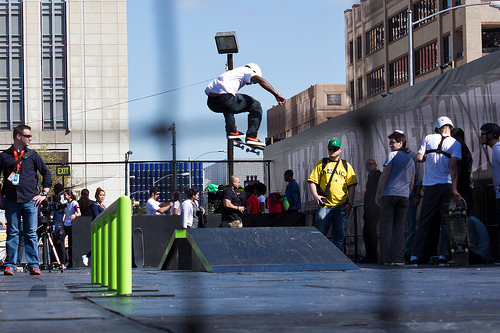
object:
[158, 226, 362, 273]
skateboard ramp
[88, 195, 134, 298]
railing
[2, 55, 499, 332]
skateboard park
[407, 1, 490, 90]
light post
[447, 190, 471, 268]
skateboard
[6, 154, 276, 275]
fence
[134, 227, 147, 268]
skateboard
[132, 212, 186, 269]
wall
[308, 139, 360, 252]
man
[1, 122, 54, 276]
man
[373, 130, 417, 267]
man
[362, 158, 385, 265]
man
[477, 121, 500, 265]
man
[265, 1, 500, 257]
building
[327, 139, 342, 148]
hat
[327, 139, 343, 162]
head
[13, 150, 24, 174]
lanyard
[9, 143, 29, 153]
neck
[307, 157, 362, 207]
shirt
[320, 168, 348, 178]
graphic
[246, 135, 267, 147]
shoe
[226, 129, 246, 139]
shoe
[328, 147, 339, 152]
sunglasses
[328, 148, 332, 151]
eye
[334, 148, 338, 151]
eye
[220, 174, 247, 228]
people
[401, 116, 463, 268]
people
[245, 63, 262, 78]
helmet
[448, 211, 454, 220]
wheel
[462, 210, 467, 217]
wheel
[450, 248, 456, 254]
wheel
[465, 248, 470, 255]
wheel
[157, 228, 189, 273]
side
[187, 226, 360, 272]
side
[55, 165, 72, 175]
exit sign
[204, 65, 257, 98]
shirt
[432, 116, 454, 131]
helmet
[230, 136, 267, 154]
skateboard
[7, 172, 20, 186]
id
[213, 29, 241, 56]
arena light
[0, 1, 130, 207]
building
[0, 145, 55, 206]
shirt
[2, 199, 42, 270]
jeans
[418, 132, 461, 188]
shirt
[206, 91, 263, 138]
jeans